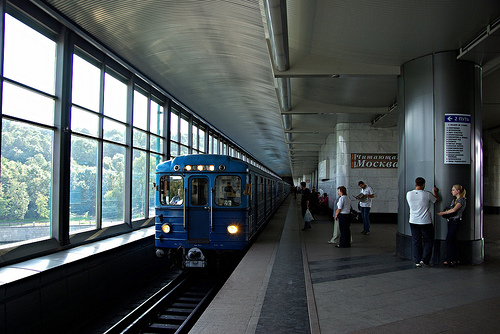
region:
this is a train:
[144, 153, 292, 283]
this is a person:
[330, 179, 358, 246]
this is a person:
[278, 170, 316, 225]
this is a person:
[353, 171, 373, 234]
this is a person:
[410, 173, 438, 265]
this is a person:
[447, 179, 472, 266]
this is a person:
[320, 183, 330, 210]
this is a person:
[307, 185, 327, 208]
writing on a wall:
[336, 143, 406, 188]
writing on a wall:
[431, 114, 466, 176]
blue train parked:
[150, 135, 299, 281]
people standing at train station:
[285, 168, 487, 267]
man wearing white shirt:
[384, 164, 454, 281]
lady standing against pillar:
[432, 180, 482, 277]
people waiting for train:
[312, 167, 359, 252]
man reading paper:
[346, 175, 386, 242]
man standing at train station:
[284, 170, 324, 250]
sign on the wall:
[342, 138, 410, 175]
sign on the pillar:
[436, 91, 494, 196]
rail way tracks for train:
[0, 109, 257, 332]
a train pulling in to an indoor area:
[6, 6, 496, 328]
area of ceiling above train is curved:
[41, 0, 291, 270]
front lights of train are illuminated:
[156, 156, 247, 250]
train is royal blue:
[153, 153, 292, 267]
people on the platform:
[290, 176, 497, 333]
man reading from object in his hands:
[350, 178, 376, 238]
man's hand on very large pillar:
[398, 52, 488, 268]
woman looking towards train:
[155, 153, 354, 268]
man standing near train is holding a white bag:
[154, 154, 314, 266]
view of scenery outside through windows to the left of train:
[1, 3, 291, 254]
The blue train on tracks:
[153, 152, 293, 302]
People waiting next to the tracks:
[296, 176, 473, 267]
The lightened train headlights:
[154, 152, 295, 274]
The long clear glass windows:
[0, 0, 292, 290]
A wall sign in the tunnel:
[445, 113, 473, 165]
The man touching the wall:
[407, 178, 442, 267]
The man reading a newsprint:
[354, 181, 375, 238]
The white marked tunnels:
[307, 125, 399, 223]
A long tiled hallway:
[185, 177, 498, 330]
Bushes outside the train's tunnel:
[2, 115, 214, 222]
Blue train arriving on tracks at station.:
[153, 153, 289, 268]